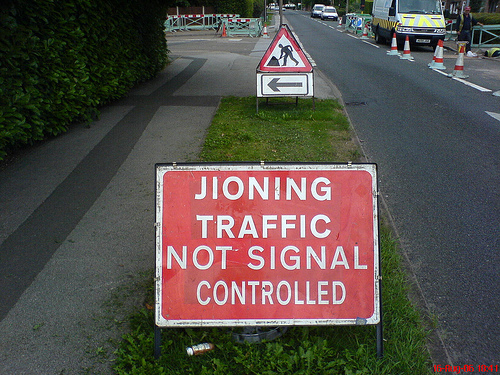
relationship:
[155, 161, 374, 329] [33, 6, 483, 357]
sign in middle of road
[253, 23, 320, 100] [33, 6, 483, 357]
sign in middle of road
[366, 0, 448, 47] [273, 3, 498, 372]
truck parked on street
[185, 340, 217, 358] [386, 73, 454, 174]
bottle on ground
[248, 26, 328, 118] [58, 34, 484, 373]
sign on ground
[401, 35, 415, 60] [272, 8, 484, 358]
cone on street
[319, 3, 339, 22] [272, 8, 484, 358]
car across street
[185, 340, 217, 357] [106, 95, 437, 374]
garbage in grass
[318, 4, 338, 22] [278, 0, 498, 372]
car parked on road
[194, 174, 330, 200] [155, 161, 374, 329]
word on sign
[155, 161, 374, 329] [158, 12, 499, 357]
sign in street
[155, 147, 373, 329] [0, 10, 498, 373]
sign in street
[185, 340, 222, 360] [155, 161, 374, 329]
bottle under sign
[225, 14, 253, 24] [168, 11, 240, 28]
stripes on fence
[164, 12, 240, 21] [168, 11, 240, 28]
stripes on fence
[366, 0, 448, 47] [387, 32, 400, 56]
truck behind cone